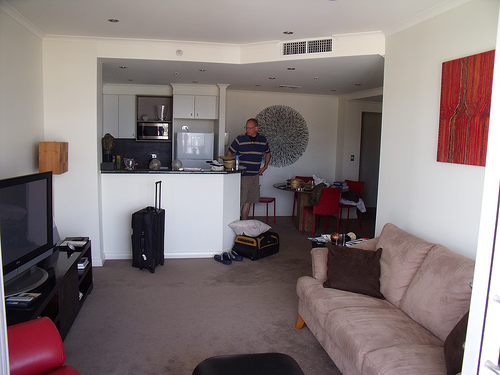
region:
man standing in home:
[222, 115, 272, 220]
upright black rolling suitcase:
[129, 181, 166, 272]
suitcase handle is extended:
[154, 180, 161, 209]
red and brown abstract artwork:
[435, 48, 495, 166]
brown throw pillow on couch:
[320, 240, 386, 301]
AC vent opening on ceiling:
[280, 34, 337, 56]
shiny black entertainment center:
[3, 239, 90, 341]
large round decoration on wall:
[255, 105, 308, 167]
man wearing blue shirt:
[227, 131, 272, 175]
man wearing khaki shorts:
[238, 173, 260, 207]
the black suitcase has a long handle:
[127, 177, 172, 275]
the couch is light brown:
[292, 221, 481, 373]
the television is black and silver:
[1, 169, 58, 299]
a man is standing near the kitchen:
[223, 111, 275, 221]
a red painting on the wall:
[433, 48, 496, 167]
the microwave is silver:
[134, 118, 171, 143]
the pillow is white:
[228, 213, 275, 240]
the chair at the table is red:
[299, 182, 345, 237]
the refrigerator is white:
[172, 127, 216, 169]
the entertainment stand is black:
[0, 235, 95, 354]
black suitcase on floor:
[129, 178, 169, 274]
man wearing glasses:
[223, 116, 273, 220]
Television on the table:
[0, 169, 57, 304]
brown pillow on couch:
[320, 238, 385, 304]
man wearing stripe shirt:
[222, 117, 274, 217]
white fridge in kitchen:
[173, 128, 217, 168]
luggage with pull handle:
[126, 180, 173, 275]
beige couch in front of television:
[295, 205, 475, 372]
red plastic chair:
[301, 186, 344, 242]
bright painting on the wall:
[433, 49, 498, 169]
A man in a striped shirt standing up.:
[227, 114, 271, 219]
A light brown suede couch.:
[295, 221, 475, 374]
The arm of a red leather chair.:
[6, 316, 78, 373]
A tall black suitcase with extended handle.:
[132, 181, 167, 274]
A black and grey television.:
[1, 170, 57, 290]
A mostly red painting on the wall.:
[434, 50, 496, 166]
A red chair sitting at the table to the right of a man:
[302, 182, 344, 237]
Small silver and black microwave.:
[135, 121, 171, 139]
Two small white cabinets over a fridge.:
[172, 91, 216, 120]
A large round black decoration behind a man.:
[250, 104, 310, 169]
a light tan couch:
[295, 224, 469, 374]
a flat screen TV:
[1, 170, 53, 297]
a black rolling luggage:
[128, 181, 168, 275]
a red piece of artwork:
[435, 50, 492, 170]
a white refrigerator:
[173, 129, 215, 174]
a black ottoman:
[192, 352, 303, 372]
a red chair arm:
[7, 317, 67, 374]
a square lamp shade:
[36, 138, 69, 175]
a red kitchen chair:
[307, 186, 344, 236]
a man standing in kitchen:
[226, 117, 271, 221]